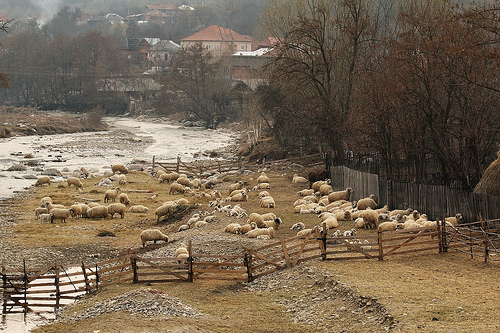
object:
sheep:
[65, 175, 86, 193]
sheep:
[38, 195, 54, 208]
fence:
[0, 219, 498, 312]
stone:
[144, 306, 159, 317]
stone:
[155, 301, 166, 309]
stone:
[111, 292, 126, 307]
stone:
[147, 287, 166, 300]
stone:
[71, 308, 83, 327]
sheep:
[257, 195, 279, 209]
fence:
[329, 162, 499, 226]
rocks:
[248, 280, 390, 324]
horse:
[307, 167, 331, 192]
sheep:
[138, 225, 172, 249]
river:
[2, 112, 242, 206]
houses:
[227, 40, 316, 90]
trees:
[7, 0, 232, 130]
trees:
[252, 0, 499, 210]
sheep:
[223, 223, 242, 235]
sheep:
[202, 214, 221, 224]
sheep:
[195, 220, 208, 229]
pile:
[75, 284, 205, 318]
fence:
[149, 150, 328, 181]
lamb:
[192, 219, 210, 229]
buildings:
[178, 22, 255, 80]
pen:
[0, 163, 469, 268]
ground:
[0, 102, 498, 330]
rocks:
[143, 231, 286, 272]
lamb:
[34, 174, 50, 186]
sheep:
[224, 192, 249, 202]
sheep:
[342, 228, 357, 238]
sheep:
[47, 207, 76, 226]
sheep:
[102, 186, 122, 204]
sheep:
[118, 191, 131, 206]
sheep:
[153, 200, 180, 225]